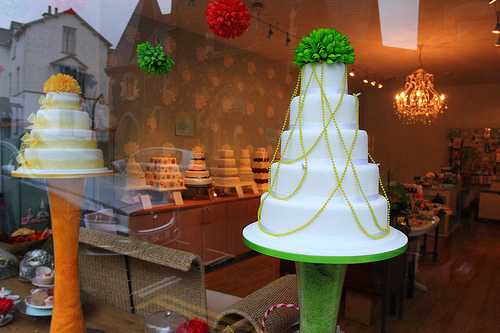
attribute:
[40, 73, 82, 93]
ribbon — yellow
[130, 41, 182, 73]
adornment — green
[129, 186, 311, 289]
cabinet — long, wooden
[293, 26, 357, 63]
adornment — green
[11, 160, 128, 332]
pedestal — orange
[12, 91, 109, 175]
cake — white, yellow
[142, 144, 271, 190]
cakes — beautiful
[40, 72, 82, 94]
adornment — orange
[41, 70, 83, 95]
decoration — green, red, yellow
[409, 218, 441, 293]
table — white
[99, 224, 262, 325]
bench — beige, white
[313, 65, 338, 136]
beads — green, decorative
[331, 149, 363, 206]
beads — green, decorative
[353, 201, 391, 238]
beads — green, decorative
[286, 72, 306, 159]
beads — green, decorative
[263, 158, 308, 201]
beads — green, decorative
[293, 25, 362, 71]
bow — green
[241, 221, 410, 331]
table — green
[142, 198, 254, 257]
case — brown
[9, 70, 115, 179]
cake — 4-tier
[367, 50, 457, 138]
chandelier — on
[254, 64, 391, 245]
cake — 5-tier, white